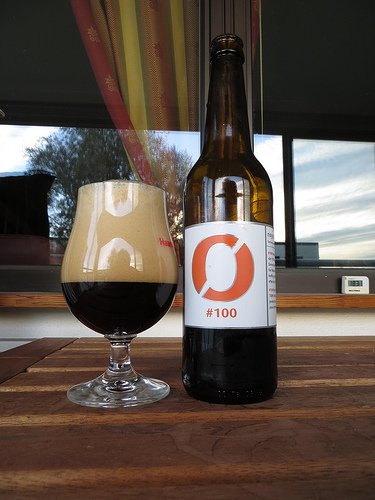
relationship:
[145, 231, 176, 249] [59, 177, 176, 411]
writing etched into glass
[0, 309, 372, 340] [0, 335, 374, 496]
wall behind table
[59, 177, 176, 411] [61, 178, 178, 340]
glass contains coke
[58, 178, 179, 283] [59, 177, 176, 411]
foam fills glass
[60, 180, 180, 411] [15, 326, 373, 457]
wine glass sits on table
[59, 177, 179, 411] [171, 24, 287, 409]
glass next to bottle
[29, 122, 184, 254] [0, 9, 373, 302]
reflection in window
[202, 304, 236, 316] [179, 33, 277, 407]
number on beer bottle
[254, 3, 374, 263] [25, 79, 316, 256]
window in restuarant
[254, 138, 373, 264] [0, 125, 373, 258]
jet trails in sky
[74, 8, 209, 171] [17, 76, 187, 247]
curtain in restuarant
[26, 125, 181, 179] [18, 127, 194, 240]
tree outside window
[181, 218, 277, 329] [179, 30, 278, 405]
label on beer bottle